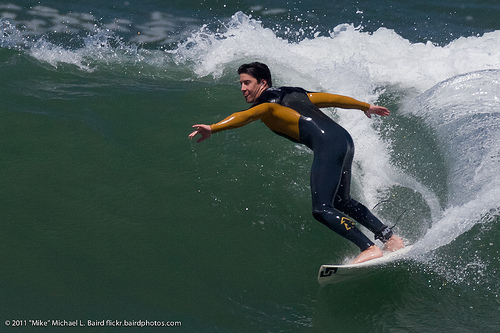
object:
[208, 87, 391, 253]
wetsuit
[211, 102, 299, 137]
panels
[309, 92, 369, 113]
sleeves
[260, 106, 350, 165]
torso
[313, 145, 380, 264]
leg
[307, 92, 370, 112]
right arm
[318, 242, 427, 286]
board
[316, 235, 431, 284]
surfboard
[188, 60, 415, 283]
surfer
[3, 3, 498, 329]
water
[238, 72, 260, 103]
face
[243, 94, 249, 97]
tongue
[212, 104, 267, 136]
arm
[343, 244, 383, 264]
feet